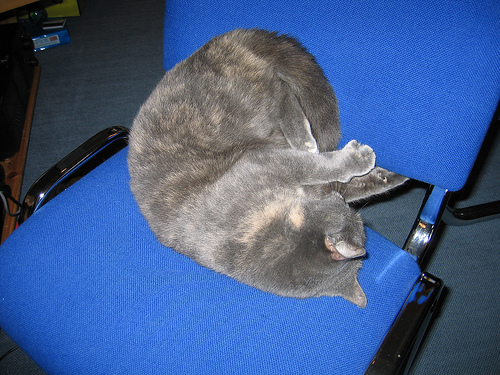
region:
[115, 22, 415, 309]
Cat is playing on chair.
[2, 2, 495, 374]
The chair is blue.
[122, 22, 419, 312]
Cat is lying on its side.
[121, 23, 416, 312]
Grey cat is playing on chair.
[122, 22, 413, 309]
Ear is perked up.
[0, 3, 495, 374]
Cat is on chair.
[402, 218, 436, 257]
Reflection of light off of metal on chair.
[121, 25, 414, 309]
The Cat is playing.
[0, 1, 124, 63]
Trash is lying on the floor.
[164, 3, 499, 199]
Paw is touching back of chair.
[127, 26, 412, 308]
Gray cat on blue chair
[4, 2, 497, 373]
Gray cat playing on blue chair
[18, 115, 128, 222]
Shiny black armrest on chair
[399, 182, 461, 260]
Chrome hinge on back of chair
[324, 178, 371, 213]
Whiskers on cat's face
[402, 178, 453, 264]
Light reflecting off of chair hinge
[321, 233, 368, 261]
Gray and pink cat's ear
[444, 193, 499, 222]
Black lever on back of chair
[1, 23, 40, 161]
Electronics sitting on a shelf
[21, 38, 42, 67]
Dials on electronic device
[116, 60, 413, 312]
a cat laying on a blue chair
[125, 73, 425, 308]
a cat sleeping on a chair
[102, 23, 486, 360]
a blue cloth chair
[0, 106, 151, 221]
a metal leg on a chair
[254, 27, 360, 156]
a cat with a long tail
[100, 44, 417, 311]
a cat playing on a chair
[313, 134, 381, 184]
a cats front foot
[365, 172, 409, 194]
a claw on a cat's foot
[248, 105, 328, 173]
a cat's back foot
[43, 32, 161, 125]
carpet on the floor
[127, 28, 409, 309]
Grey cat laying on blue chair.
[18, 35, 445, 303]
a grey cat in a chair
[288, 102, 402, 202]
a grey cat paw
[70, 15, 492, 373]
a cat laying on a blue chair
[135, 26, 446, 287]
a big grey cat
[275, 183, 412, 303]
a grey cat head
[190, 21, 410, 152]
a grey cat tail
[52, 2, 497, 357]
a chair that is blue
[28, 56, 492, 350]
a grey cat in a blue chair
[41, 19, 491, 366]
a blue chair with a grey cat on it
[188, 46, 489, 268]
a cat scratching a chir